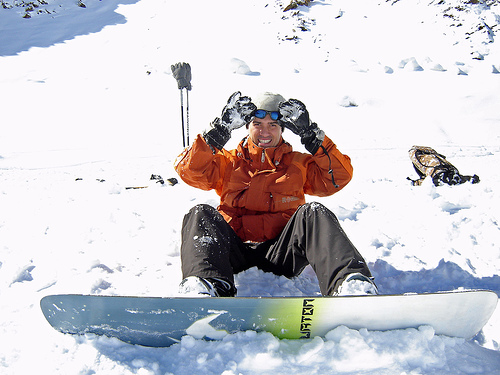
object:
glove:
[276, 98, 325, 155]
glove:
[202, 91, 257, 156]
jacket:
[173, 134, 353, 242]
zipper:
[261, 152, 265, 162]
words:
[299, 299, 315, 339]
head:
[248, 92, 287, 148]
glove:
[171, 63, 187, 86]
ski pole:
[180, 88, 185, 147]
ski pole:
[186, 90, 190, 146]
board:
[40, 290, 498, 348]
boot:
[178, 276, 237, 297]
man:
[174, 91, 379, 297]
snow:
[0, 0, 499, 375]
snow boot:
[332, 272, 379, 296]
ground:
[74, 126, 164, 251]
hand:
[277, 97, 313, 136]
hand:
[217, 88, 258, 134]